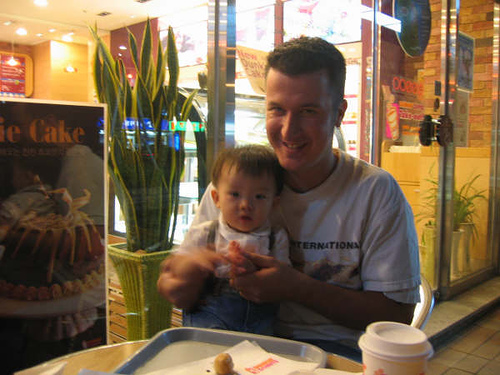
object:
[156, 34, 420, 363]
man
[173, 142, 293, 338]
baby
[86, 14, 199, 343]
plant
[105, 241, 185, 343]
pot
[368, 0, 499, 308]
frame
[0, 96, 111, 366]
sign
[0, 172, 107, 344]
cake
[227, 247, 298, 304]
hands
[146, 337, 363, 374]
napkin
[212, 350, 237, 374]
donut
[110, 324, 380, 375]
tray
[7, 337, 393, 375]
table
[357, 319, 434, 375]
cup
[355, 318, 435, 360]
lid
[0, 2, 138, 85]
light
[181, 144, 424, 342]
shirt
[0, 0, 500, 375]
restaraunt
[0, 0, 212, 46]
ceiling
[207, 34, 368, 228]
camera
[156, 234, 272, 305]
hand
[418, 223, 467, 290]
vase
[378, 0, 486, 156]
sign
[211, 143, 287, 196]
hair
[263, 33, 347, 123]
hair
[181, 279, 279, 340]
jeans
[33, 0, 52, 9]
lights